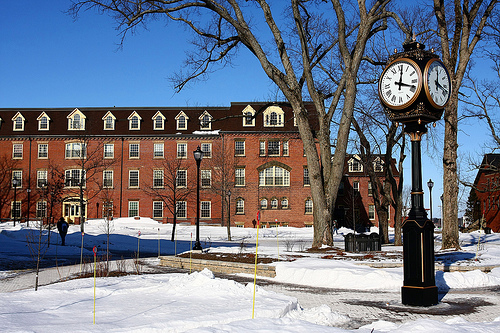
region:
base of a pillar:
[405, 285, 420, 299]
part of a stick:
[229, 232, 271, 285]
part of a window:
[261, 169, 278, 179]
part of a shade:
[56, 211, 125, 279]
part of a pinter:
[164, 217, 216, 298]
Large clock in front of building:
[368, 36, 466, 331]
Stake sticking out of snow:
[232, 205, 277, 319]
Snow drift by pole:
[242, 285, 308, 330]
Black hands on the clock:
[378, 62, 418, 94]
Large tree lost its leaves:
[89, 6, 370, 242]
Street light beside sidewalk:
[187, 139, 214, 252]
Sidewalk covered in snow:
[180, 257, 382, 298]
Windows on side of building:
[250, 134, 297, 221]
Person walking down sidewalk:
[47, 203, 79, 249]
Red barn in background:
[466, 140, 498, 220]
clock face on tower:
[371, 57, 421, 116]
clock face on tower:
[423, 64, 444, 114]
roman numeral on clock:
[398, 96, 402, 108]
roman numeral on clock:
[396, 94, 406, 101]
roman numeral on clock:
[407, 85, 419, 95]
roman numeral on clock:
[384, 82, 391, 89]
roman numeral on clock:
[407, 67, 414, 75]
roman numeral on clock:
[381, 73, 391, 80]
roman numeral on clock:
[406, 70, 415, 77]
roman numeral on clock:
[381, 83, 388, 89]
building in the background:
[1, 102, 286, 228]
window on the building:
[123, 138, 150, 165]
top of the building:
[112, 105, 169, 144]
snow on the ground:
[154, 297, 221, 329]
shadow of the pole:
[138, 291, 188, 318]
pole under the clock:
[376, 143, 457, 210]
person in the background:
[53, 201, 88, 250]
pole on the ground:
[173, 141, 220, 238]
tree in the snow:
[275, 126, 360, 239]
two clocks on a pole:
[374, 68, 454, 108]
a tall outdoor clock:
[377, 40, 456, 302]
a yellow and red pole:
[247, 202, 262, 327]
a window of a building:
[233, 136, 246, 155]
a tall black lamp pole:
[424, 177, 439, 219]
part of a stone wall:
[161, 254, 273, 279]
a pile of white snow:
[270, 255, 396, 293]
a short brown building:
[467, 155, 499, 227]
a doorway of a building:
[64, 197, 87, 222]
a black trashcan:
[345, 233, 356, 250]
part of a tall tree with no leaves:
[64, 2, 406, 245]